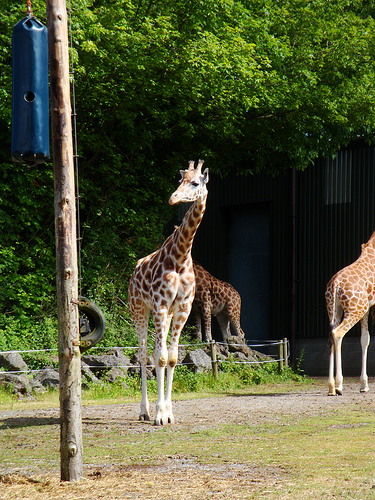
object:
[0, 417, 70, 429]
shadow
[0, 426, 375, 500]
ground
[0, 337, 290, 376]
fence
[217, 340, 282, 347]
wire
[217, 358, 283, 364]
wire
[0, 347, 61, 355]
wire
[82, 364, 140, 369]
wire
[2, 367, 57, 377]
wire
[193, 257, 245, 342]
giraffe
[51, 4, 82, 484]
pole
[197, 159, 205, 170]
horns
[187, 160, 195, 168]
horns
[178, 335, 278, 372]
rocks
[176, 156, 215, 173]
knubs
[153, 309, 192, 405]
white legs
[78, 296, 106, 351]
tube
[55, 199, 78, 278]
post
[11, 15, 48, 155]
bag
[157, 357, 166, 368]
brown spot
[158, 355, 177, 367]
knees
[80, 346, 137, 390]
gray rocks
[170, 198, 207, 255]
neck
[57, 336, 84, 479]
pole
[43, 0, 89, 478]
pole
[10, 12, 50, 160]
bag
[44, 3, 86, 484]
pole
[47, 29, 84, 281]
pole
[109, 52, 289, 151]
trees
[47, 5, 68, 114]
pole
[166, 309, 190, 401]
leg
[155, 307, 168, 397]
leg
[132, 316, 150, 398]
leg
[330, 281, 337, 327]
tail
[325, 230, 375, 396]
giraffe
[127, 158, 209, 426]
giraffe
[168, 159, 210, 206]
head